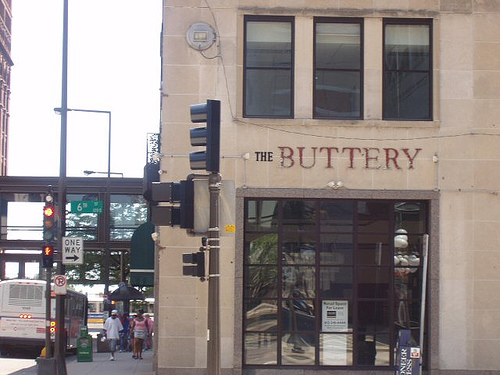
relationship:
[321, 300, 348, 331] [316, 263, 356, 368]
paper on door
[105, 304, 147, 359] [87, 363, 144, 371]
couple walking on sidewalk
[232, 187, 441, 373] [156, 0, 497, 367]
door on building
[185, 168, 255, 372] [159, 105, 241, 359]
pole on building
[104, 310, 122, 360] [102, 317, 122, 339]
pedestrian wearing white top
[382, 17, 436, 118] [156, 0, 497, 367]
window on building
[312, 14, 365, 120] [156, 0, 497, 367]
window on building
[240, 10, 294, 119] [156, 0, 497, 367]
window on building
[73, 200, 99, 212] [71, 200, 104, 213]
6th street on 6th street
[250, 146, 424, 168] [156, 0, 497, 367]
buttery on building